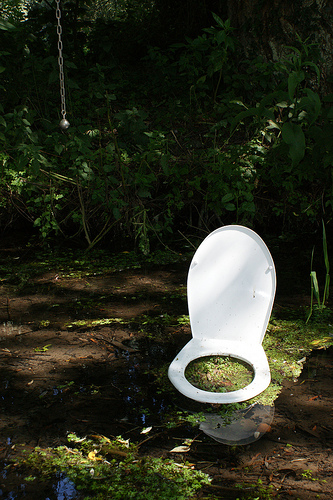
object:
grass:
[0, 0, 333, 500]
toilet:
[166, 224, 276, 406]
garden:
[0, 0, 333, 500]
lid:
[167, 225, 277, 405]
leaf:
[239, 198, 257, 216]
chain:
[54, 1, 66, 119]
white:
[168, 224, 276, 405]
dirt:
[0, 245, 333, 499]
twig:
[87, 332, 127, 353]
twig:
[42, 335, 68, 343]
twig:
[14, 354, 58, 363]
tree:
[0, 0, 333, 257]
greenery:
[0, 0, 332, 259]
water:
[0, 284, 333, 498]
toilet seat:
[167, 338, 272, 405]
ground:
[0, 230, 333, 500]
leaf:
[118, 198, 134, 209]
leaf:
[109, 202, 125, 220]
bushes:
[0, 0, 333, 249]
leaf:
[114, 144, 130, 163]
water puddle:
[0, 267, 333, 500]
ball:
[59, 118, 71, 133]